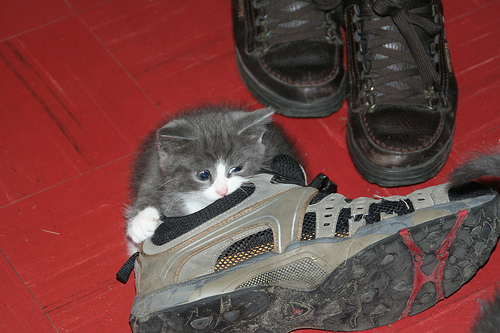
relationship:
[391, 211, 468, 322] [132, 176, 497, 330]
x on bottom of shoe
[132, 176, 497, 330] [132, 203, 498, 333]
shoe has sole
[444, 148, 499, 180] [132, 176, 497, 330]
tail on shoe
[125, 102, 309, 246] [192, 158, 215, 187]
kitten has eye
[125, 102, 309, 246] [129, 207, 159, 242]
kitten has paw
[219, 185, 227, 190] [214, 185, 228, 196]
fur on nose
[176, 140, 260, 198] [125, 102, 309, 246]
face of kitten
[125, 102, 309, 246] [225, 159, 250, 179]
kitten has eye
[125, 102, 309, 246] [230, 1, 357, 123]
kitten near shoe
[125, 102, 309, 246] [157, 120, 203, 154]
kitten has ear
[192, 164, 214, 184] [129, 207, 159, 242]
eye has paw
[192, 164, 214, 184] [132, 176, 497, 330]
eye chews shoe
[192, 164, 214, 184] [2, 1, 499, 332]
eye sits on floor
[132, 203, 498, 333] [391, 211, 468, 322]
sole has designs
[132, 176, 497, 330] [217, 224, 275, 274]
shoe has mesh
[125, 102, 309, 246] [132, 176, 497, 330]
kitten in shoe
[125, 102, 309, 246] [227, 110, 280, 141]
kitten has ear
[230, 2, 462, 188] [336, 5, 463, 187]
pair of shoe